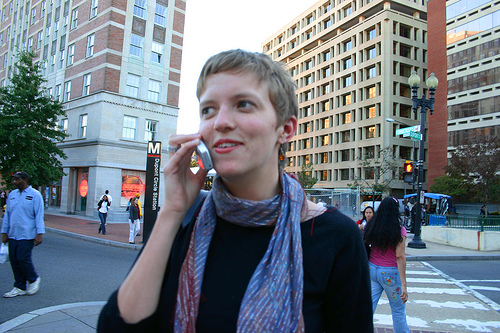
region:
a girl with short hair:
[188, 45, 303, 202]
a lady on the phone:
[186, 47, 301, 190]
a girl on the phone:
[182, 46, 310, 205]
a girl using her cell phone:
[165, 43, 312, 218]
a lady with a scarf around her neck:
[95, 49, 373, 331]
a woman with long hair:
[357, 190, 412, 331]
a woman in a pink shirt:
[366, 192, 412, 331]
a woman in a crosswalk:
[365, 192, 411, 332]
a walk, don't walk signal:
[392, 147, 426, 201]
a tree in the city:
[0, 37, 72, 233]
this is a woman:
[65, 40, 348, 330]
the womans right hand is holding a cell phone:
[173, 125, 208, 189]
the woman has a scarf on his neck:
[206, 187, 299, 331]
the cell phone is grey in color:
[198, 145, 206, 164]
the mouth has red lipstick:
[213, 138, 241, 152]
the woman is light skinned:
[249, 124, 266, 139]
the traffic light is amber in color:
[405, 165, 415, 172]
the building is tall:
[78, 5, 175, 116]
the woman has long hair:
[378, 209, 394, 231]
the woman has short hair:
[198, 55, 263, 86]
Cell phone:
[184, 134, 225, 183]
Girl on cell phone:
[147, 42, 325, 230]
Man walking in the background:
[3, 160, 50, 263]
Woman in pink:
[355, 195, 417, 302]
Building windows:
[301, 51, 362, 141]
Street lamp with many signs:
[400, 68, 450, 249]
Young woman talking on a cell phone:
[130, 55, 331, 300]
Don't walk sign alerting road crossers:
[400, 160, 415, 191]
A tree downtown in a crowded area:
[1, 51, 68, 173]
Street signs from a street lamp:
[383, 71, 448, 170]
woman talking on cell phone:
[93, 45, 386, 330]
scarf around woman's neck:
[171, 172, 313, 331]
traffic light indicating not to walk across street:
[401, 160, 418, 185]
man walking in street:
[2, 170, 50, 296]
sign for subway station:
[136, 138, 163, 248]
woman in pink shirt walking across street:
[365, 195, 412, 331]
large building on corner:
[6, 5, 188, 222]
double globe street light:
[402, 69, 439, 249]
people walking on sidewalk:
[94, 185, 141, 243]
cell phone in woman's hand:
[192, 132, 215, 174]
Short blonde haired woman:
[181, 45, 321, 101]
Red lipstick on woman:
[205, 135, 250, 153]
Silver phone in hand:
[189, 137, 214, 175]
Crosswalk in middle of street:
[424, 261, 488, 326]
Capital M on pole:
[144, 135, 164, 158]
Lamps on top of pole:
[399, 66, 454, 113]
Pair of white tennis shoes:
[3, 276, 58, 304]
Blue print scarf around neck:
[203, 183, 325, 332]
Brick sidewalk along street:
[57, 215, 89, 231]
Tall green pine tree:
[1, 47, 73, 187]